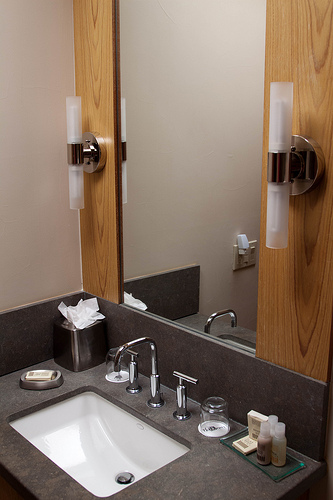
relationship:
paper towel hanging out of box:
[56, 296, 106, 332] [46, 317, 111, 374]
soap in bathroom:
[22, 367, 53, 381] [10, 13, 322, 488]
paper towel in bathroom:
[52, 298, 109, 330] [10, 13, 322, 488]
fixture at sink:
[170, 369, 198, 421] [10, 385, 191, 498]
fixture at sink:
[124, 349, 142, 394] [10, 385, 191, 498]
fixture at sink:
[112, 335, 164, 407] [10, 385, 191, 498]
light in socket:
[231, 233, 254, 261] [233, 241, 248, 268]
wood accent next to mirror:
[69, 1, 124, 301] [114, 0, 256, 301]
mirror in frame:
[170, 174, 228, 283] [69, 16, 319, 356]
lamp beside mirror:
[256, 71, 320, 258] [160, 49, 277, 151]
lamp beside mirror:
[59, 90, 109, 213] [160, 49, 277, 151]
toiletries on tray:
[44, 290, 292, 470] [224, 422, 311, 481]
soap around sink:
[24, 369, 55, 381] [4, 392, 194, 487]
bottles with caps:
[251, 411, 293, 469] [257, 419, 285, 434]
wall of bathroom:
[1, 6, 95, 346] [9, 25, 302, 495]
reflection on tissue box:
[67, 326, 92, 370] [53, 316, 108, 373]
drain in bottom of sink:
[103, 468, 139, 482] [0, 373, 188, 480]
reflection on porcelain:
[44, 430, 97, 463] [254, 78, 293, 251]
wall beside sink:
[1, 6, 64, 284] [10, 385, 191, 498]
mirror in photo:
[114, 0, 268, 359] [0, 0, 333, 499]